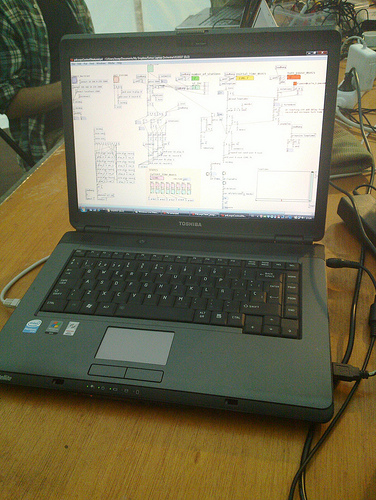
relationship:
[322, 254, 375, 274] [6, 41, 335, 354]
cable inside laptop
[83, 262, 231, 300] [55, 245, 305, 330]
letters on keyboard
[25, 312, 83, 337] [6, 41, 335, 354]
stickers on laptop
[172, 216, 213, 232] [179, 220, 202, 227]
nameer of brand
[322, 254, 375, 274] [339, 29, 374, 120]
cords plugged on powerstrip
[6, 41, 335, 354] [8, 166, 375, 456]
laptop on desk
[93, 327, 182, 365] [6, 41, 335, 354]
mousepad on laptop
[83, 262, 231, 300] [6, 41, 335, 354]
keys on laptop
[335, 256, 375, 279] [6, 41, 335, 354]
cord in laptop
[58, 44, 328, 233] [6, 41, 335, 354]
screen of laptop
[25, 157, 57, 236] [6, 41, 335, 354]
wooden desk under laptop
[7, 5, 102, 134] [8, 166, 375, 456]
person behind desk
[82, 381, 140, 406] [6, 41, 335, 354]
lights on laptop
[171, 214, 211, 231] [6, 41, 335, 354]
brand of laptop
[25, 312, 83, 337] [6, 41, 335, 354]
labels on laptop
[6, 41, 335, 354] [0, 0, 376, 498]
laptop on desk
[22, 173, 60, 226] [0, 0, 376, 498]
woodgrain on desk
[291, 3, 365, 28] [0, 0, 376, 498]
cables on desk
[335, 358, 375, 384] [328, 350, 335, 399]
black cable in usbport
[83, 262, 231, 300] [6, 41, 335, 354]
letters on laptop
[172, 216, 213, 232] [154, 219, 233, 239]
name of computercompany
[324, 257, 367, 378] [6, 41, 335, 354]
blackcords plugged in to computer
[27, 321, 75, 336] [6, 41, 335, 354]
brand stickers on laptop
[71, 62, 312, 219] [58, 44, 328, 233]
document displayed on screen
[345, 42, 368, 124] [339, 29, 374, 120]
cords plugged in to surge protector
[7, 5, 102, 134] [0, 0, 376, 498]
person standing near desk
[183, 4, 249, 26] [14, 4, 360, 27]
laptop in background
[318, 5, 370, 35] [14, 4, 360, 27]
tangle cords in background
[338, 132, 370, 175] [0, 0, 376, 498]
clothing on desk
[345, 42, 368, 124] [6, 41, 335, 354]
cords by laptop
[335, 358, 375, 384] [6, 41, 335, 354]
plugs inserted in laptop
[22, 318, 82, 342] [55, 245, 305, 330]
logos bellow keyboard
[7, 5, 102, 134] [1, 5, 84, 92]
person in plaidshirt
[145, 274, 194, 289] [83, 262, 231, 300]
keys have white print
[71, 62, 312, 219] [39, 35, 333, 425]
diagram on laptop